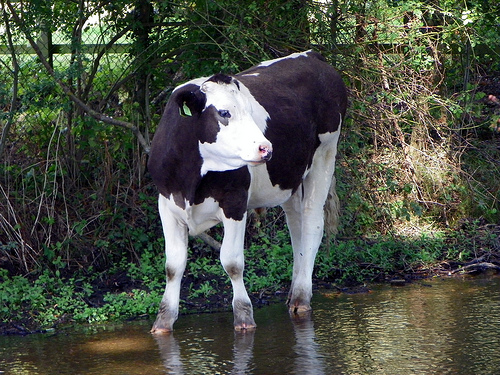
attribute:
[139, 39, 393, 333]
cow — black, white, standing, young, muddy, spotted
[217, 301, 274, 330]
hoof — brown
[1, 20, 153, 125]
fence — metal, wire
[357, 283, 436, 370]
sun — shining, brown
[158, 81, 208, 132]
ear — green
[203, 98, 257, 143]
eye — small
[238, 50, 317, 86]
spot — white, dark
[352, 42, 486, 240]
plants — growing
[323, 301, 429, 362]
water — small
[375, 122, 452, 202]
weeds — green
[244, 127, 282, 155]
nostril — tiny